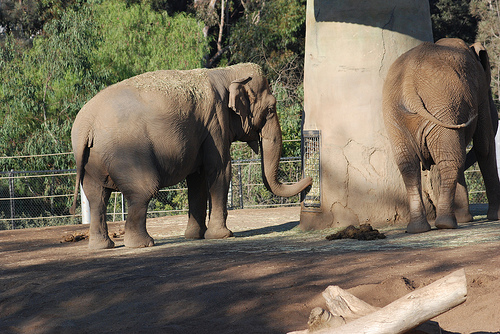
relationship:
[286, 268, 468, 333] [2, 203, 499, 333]
branch on ground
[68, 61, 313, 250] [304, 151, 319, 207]
elephant eating hay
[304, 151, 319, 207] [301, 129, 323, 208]
hay in feeder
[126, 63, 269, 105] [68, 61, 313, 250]
hay on elephant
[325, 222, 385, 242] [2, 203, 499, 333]
dung on ground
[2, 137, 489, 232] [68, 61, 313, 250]
fence behind elephant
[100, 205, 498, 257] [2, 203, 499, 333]
hay on ground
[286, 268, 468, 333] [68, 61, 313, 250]
branch near elephant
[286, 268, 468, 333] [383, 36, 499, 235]
branch near elephant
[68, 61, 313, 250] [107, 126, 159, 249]
elephant has leg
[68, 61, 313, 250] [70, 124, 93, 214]
elephant has tail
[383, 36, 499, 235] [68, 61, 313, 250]
elephant right of elephant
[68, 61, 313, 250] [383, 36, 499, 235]
elephant left of elephant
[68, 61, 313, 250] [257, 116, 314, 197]
elephant has trunk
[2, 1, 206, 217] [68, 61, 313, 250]
tree behind elephant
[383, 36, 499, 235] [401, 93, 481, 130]
elephant has tail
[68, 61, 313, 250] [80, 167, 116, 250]
elephant has hind leg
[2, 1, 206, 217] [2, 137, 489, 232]
tree behind fence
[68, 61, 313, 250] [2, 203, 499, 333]
elephant on ground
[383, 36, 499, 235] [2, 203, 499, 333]
elephant on ground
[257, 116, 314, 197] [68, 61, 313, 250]
trunk on elephant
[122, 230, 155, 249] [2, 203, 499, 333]
foot on ground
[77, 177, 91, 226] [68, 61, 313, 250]
pole next to elephant